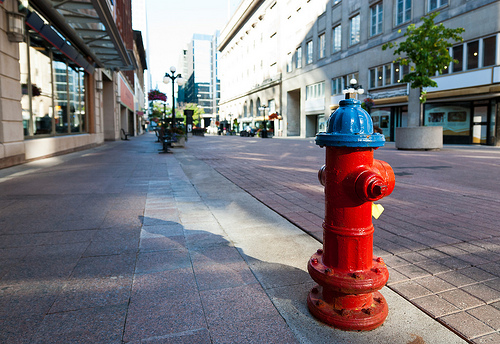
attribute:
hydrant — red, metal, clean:
[309, 91, 398, 331]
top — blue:
[314, 92, 387, 148]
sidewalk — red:
[3, 124, 465, 342]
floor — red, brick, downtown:
[178, 129, 499, 343]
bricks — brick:
[419, 246, 458, 269]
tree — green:
[380, 13, 466, 102]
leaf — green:
[417, 49, 420, 54]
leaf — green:
[428, 41, 431, 48]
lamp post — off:
[161, 65, 184, 145]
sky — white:
[145, 0, 242, 90]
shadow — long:
[139, 216, 316, 320]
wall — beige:
[454, 8, 499, 35]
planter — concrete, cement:
[396, 126, 444, 151]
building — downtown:
[2, 2, 148, 168]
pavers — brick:
[434, 255, 496, 297]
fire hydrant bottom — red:
[308, 147, 395, 331]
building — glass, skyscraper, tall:
[176, 31, 221, 133]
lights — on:
[395, 61, 404, 84]